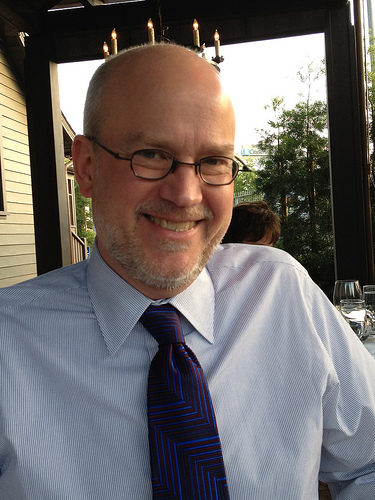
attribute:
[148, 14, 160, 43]
candle — here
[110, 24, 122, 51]
candle — here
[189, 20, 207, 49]
candle — here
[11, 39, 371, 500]
man — smiling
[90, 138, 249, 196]
glasses — wire, small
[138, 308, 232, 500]
tie — black, red, blue, patterned, purple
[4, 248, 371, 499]
shirt — blue, white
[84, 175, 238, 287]
beard — trimmed, gray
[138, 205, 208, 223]
moustache — trimmed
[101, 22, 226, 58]
candles — faux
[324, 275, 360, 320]
water glass — large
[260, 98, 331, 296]
tree — green, leafy, tall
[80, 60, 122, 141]
hair — light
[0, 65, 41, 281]
siding — yellow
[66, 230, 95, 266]
railing — wooden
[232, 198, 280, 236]
hair — brown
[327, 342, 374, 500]
sleeves — long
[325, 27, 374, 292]
pole — wooden, tall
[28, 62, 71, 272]
pole — wooden, tall